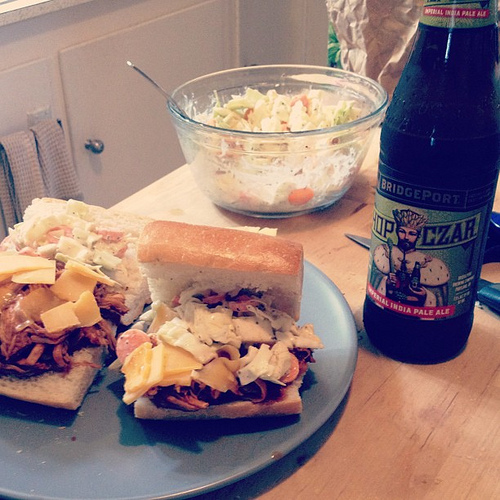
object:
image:
[372, 208, 449, 321]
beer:
[361, 0, 500, 366]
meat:
[17, 322, 67, 369]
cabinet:
[1, 3, 241, 208]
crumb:
[58, 425, 66, 432]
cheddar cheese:
[120, 343, 201, 406]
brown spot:
[271, 448, 283, 461]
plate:
[2, 258, 355, 499]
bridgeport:
[380, 178, 462, 208]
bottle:
[359, 2, 496, 365]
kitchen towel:
[29, 119, 84, 204]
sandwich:
[125, 219, 302, 423]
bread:
[135, 219, 304, 323]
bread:
[0, 344, 105, 410]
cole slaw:
[199, 90, 360, 189]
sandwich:
[3, 182, 160, 417]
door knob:
[86, 137, 107, 155]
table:
[3, 125, 500, 500]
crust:
[137, 219, 301, 273]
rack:
[0, 118, 66, 154]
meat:
[96, 283, 130, 316]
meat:
[157, 391, 206, 417]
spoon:
[125, 60, 193, 122]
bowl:
[167, 61, 387, 220]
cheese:
[0, 252, 101, 343]